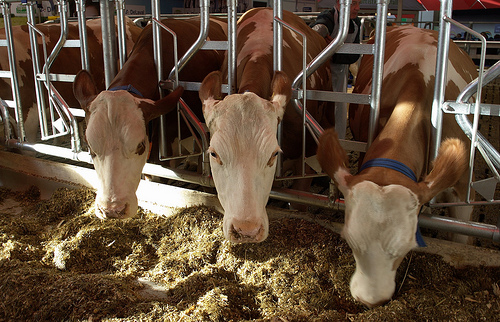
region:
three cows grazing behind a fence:
[20, 67, 467, 310]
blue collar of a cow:
[357, 148, 423, 199]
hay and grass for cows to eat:
[22, 264, 331, 319]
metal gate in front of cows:
[12, 4, 92, 71]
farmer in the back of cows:
[312, 0, 370, 186]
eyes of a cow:
[199, 143, 285, 168]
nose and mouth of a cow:
[214, 212, 286, 253]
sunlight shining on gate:
[45, 142, 77, 159]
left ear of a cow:
[427, 134, 474, 222]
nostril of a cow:
[117, 199, 132, 221]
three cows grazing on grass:
[73, 6, 482, 320]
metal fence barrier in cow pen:
[2, 3, 499, 239]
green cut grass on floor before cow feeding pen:
[154, 250, 304, 316]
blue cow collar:
[352, 158, 432, 249]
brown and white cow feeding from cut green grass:
[313, 23, 482, 320]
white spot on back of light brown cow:
[391, 30, 429, 96]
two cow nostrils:
[221, 215, 266, 243]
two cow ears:
[189, 68, 290, 115]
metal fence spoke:
[1, 6, 29, 136]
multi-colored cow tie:
[167, 90, 207, 153]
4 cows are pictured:
[4, 8, 463, 212]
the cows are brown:
[1, 0, 490, 198]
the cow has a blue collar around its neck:
[347, 133, 487, 249]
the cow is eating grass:
[305, 124, 474, 310]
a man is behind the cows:
[314, 1, 429, 120]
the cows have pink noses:
[69, 171, 271, 246]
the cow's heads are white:
[79, 76, 489, 296]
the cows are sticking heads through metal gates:
[3, 1, 482, 213]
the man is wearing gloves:
[307, 11, 339, 48]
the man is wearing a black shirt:
[312, 7, 381, 74]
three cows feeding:
[54, 4, 494, 319]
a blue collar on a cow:
[356, 144, 422, 190]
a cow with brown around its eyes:
[206, 137, 283, 174]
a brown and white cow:
[308, 27, 475, 315]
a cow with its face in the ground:
[310, 127, 496, 310]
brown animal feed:
[4, 203, 358, 315]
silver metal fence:
[21, 5, 498, 122]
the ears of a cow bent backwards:
[181, 70, 306, 115]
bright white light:
[16, 127, 198, 229]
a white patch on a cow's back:
[212, 2, 301, 64]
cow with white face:
[189, 81, 289, 253]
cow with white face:
[326, 165, 425, 310]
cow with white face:
[64, 79, 166, 221]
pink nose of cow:
[224, 219, 274, 244]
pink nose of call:
[80, 179, 147, 238]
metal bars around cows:
[24, 5, 491, 215]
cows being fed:
[21, 206, 383, 320]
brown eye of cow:
[115, 139, 148, 161]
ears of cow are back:
[190, 62, 305, 119]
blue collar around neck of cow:
[351, 144, 433, 224]